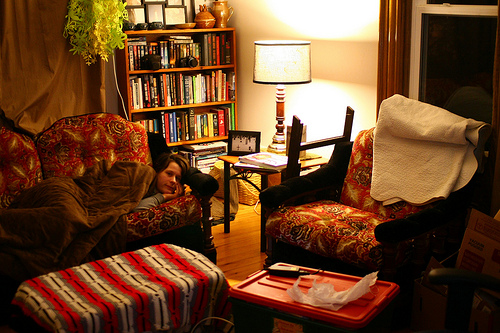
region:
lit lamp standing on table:
[253, 37, 311, 153]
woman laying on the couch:
[23, 155, 185, 252]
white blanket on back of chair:
[368, 92, 485, 207]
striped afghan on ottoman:
[16, 243, 229, 330]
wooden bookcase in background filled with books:
[117, 26, 238, 178]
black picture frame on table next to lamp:
[225, 127, 260, 153]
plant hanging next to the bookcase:
[63, 0, 127, 64]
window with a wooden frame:
[377, 1, 499, 133]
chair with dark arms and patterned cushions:
[259, 125, 489, 291]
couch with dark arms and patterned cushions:
[2, 112, 217, 276]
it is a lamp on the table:
[249, 37, 316, 82]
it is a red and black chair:
[296, 193, 401, 249]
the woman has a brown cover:
[35, 180, 90, 222]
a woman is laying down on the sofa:
[57, 159, 186, 242]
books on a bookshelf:
[151, 47, 222, 128]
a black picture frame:
[229, 124, 264, 155]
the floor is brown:
[226, 241, 248, 273]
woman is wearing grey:
[139, 192, 164, 208]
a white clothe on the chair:
[378, 116, 452, 190]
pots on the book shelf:
[199, 8, 223, 29]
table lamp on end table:
[254, 39, 309, 154]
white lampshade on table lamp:
[252, 39, 312, 84]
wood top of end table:
[215, 142, 321, 172]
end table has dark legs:
[220, 160, 233, 235]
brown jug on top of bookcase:
[195, 6, 213, 28]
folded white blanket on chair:
[372, 95, 484, 202]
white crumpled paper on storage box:
[287, 271, 381, 313]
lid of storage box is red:
[227, 261, 399, 328]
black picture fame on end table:
[225, 128, 260, 154]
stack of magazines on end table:
[230, 149, 287, 172]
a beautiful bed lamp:
[240, 32, 314, 91]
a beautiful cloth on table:
[24, 240, 214, 323]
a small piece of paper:
[281, 268, 381, 303]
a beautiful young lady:
[17, 155, 208, 244]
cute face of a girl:
[146, 151, 192, 205]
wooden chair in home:
[279, 112, 372, 189]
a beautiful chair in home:
[270, 105, 480, 257]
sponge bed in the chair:
[274, 198, 414, 267]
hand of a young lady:
[166, 182, 192, 199]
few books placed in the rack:
[129, 57, 246, 143]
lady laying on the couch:
[22, 138, 227, 237]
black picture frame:
[213, 117, 268, 154]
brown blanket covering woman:
[2, 144, 194, 259]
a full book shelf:
[120, 22, 255, 177]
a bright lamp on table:
[239, 25, 314, 162]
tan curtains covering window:
[3, 7, 126, 135]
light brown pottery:
[178, 3, 234, 35]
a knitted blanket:
[11, 220, 226, 331]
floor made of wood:
[177, 167, 297, 322]